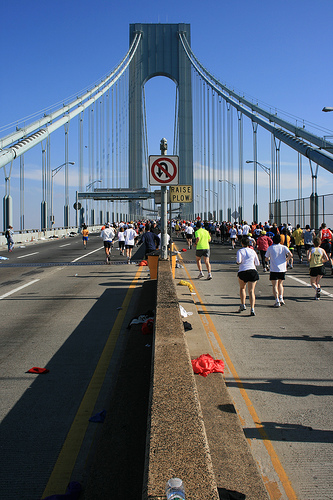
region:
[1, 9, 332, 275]
This is the Verazzano Bridge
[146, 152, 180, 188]
No U-turn allowed sign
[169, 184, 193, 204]
The Raise Plow sign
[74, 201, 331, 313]
People are running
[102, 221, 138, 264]
Three people in white shirts and black shorts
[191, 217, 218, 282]
He's in a neon green shirt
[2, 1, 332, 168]
The sky is blue and cloudless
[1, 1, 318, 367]
It's a sunny day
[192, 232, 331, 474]
The people are making shadows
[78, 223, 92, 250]
He has an orange shirt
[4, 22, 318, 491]
running across bridge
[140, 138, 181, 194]
sign depicipting no u-turn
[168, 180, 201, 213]
sign indicating to raise plow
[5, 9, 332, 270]
beautiful bridge span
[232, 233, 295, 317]
runners in white shirts and black shorts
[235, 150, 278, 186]
lightpost on bridge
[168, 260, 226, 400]
shirts discarded along running route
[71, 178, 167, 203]
overhead sign for oncoming traffic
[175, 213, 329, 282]
large group of marathon runners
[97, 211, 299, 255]
group of marathon runners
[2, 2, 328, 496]
many people running over a tall gray bridge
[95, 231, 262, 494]
cement barrier between directions for traffic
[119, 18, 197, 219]
tall gray cement tower holding supports for bridge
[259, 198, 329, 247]
fencing along one side of a bridge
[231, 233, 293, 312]
two women running with black bottoms and white tops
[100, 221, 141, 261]
three people running with white hats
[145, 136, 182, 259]
traffic sign on a metal pole for no U turns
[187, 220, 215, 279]
man running with yellow shirt and black shorts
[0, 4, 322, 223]
blue sky with a few white clouds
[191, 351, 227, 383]
red article of clothing left on the traffic barrier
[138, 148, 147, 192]
red and white sign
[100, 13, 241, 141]
bridge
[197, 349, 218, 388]
orange jacket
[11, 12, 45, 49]
white clouds in blue sky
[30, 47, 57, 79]
white clouds in blue sky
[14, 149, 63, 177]
white clouds in blue sky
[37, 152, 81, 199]
white clouds in blue sky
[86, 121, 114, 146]
white clouds in blue sky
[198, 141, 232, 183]
white clouds in blue sky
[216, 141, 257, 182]
white clouds in blue sky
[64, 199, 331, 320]
people are running on the bridge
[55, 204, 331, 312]
they are running a race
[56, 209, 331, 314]
they are running a marathon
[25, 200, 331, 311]
they are running a 5k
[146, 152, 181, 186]
a no u-turn sign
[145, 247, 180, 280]
a large plastic container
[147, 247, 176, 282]
a large yellow bin with a black lid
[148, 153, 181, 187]
the sign is white and has a red and black emblem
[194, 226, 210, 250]
a bright neon green tee shirt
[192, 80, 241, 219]
the steel wires of a bridge